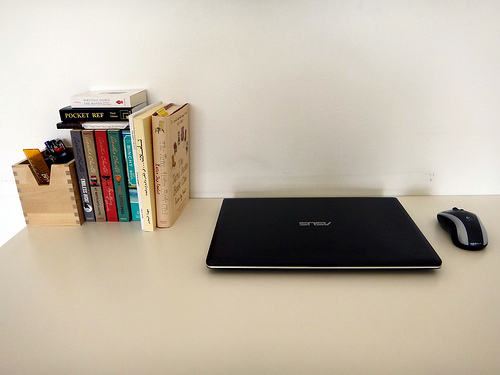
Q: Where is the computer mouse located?
A: Right of the laptop.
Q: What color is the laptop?
A: Black.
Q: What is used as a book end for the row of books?
A: A small wooden box.